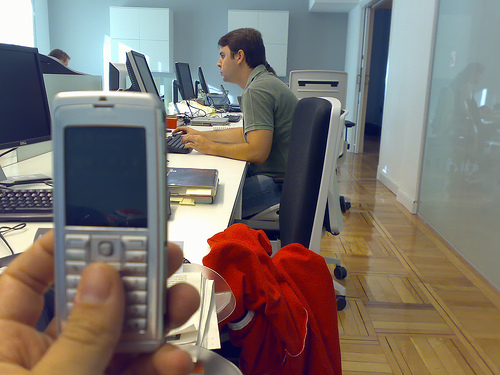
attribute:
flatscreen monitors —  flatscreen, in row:
[171, 77, 206, 110]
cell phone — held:
[47, 87, 168, 357]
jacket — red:
[199, 219, 345, 374]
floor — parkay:
[312, 146, 498, 371]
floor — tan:
[320, 132, 498, 373]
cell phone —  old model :
[39, 96, 246, 324]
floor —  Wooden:
[344, 155, 498, 369]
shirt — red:
[198, 224, 343, 372]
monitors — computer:
[8, 44, 229, 161]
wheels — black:
[328, 250, 346, 312]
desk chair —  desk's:
[263, 93, 370, 313]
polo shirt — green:
[241, 78, 296, 168]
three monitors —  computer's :
[124, 48, 209, 96]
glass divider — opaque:
[368, 9, 496, 207]